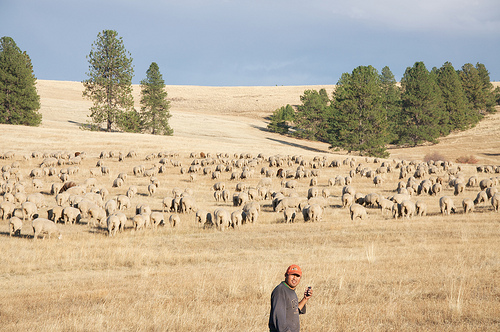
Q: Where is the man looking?
A: At the camera.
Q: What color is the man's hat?
A: Orange.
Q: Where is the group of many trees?
A: Back right.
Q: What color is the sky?
A: Blue.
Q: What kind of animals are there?
A: Sheep.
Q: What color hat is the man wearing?
A: Orange.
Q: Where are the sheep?
A: In a field.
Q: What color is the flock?
A: Brown.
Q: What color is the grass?
A: Brown.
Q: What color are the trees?
A: Green.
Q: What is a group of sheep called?
A: A Herd.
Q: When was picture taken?
A: During the daytime.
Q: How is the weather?
A: Clear and sunny.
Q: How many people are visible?
A: One.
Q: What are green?
A: Trees.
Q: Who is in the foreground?
A: A man.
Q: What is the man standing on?
A: Grass.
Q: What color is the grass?
A: Yellow.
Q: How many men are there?
A: One.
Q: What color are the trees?
A: Green.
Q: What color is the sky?
A: Blue.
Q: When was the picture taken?
A: Daytime.